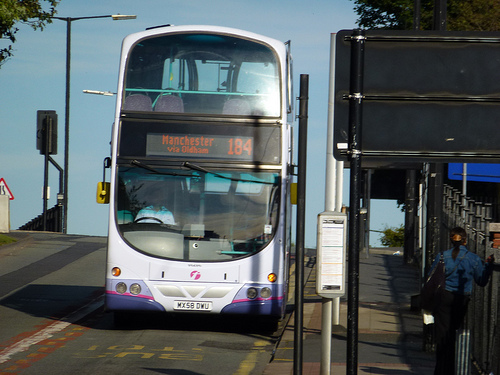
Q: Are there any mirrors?
A: Yes, there is a mirror.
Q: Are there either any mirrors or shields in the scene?
A: Yes, there is a mirror.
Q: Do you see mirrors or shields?
A: Yes, there is a mirror.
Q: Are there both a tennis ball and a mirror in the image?
A: No, there is a mirror but no tennis balls.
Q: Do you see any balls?
A: No, there are no balls.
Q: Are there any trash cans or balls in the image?
A: No, there are no balls or trash cans.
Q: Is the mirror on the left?
A: Yes, the mirror is on the left of the image.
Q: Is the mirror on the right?
A: No, the mirror is on the left of the image.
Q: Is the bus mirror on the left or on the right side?
A: The mirror is on the left of the image.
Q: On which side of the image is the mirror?
A: The mirror is on the left of the image.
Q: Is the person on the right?
A: Yes, the person is on the right of the image.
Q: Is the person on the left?
A: No, the person is on the right of the image.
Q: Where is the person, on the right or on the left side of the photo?
A: The person is on the right of the image.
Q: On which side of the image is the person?
A: The person is on the right of the image.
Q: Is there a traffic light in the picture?
A: Yes, there is a traffic light.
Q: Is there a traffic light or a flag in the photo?
A: Yes, there is a traffic light.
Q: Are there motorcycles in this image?
A: No, there are no motorcycles.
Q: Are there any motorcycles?
A: No, there are no motorcycles.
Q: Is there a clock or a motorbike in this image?
A: No, there are no motorcycles or clocks.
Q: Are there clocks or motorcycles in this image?
A: No, there are no motorcycles or clocks.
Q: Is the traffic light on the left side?
A: Yes, the traffic light is on the left of the image.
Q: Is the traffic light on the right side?
A: No, the traffic light is on the left of the image.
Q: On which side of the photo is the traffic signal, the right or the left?
A: The traffic signal is on the left of the image.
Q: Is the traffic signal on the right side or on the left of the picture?
A: The traffic signal is on the left of the image.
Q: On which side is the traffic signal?
A: The traffic signal is on the left of the image.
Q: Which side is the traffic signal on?
A: The traffic signal is on the left of the image.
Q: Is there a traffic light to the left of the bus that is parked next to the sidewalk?
A: Yes, there is a traffic light to the left of the bus.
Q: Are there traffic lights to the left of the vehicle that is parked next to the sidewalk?
A: Yes, there is a traffic light to the left of the bus.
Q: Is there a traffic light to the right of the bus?
A: No, the traffic light is to the left of the bus.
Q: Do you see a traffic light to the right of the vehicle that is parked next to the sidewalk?
A: No, the traffic light is to the left of the bus.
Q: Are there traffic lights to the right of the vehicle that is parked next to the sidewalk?
A: No, the traffic light is to the left of the bus.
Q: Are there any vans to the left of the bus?
A: No, there is a traffic light to the left of the bus.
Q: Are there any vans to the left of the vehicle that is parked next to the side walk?
A: No, there is a traffic light to the left of the bus.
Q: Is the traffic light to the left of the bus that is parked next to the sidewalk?
A: Yes, the traffic light is to the left of the bus.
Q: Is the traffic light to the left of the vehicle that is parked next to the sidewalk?
A: Yes, the traffic light is to the left of the bus.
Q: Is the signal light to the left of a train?
A: No, the signal light is to the left of the bus.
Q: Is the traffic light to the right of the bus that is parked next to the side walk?
A: No, the traffic light is to the left of the bus.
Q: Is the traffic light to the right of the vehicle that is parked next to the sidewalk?
A: No, the traffic light is to the left of the bus.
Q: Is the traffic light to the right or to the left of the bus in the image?
A: The traffic light is to the left of the bus.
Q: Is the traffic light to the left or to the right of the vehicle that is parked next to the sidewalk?
A: The traffic light is to the left of the bus.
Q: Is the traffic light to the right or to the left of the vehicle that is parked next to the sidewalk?
A: The traffic light is to the left of the bus.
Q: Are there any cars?
A: No, there are no cars.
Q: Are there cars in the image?
A: No, there are no cars.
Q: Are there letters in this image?
A: Yes, there are letters.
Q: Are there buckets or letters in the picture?
A: Yes, there are letters.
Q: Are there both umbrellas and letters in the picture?
A: No, there are letters but no umbrellas.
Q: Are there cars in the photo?
A: No, there are no cars.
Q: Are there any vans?
A: No, there are no vans.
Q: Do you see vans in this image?
A: No, there are no vans.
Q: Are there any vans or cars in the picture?
A: No, there are no vans or cars.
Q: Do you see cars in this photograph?
A: No, there are no cars.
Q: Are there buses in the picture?
A: Yes, there is a bus.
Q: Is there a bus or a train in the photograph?
A: Yes, there is a bus.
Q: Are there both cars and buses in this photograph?
A: No, there is a bus but no cars.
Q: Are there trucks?
A: No, there are no trucks.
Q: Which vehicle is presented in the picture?
A: The vehicle is a bus.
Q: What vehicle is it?
A: The vehicle is a bus.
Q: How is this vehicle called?
A: This is a bus.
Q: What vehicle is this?
A: This is a bus.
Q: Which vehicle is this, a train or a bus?
A: This is a bus.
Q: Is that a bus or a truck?
A: That is a bus.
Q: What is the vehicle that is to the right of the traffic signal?
A: The vehicle is a bus.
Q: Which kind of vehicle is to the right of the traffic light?
A: The vehicle is a bus.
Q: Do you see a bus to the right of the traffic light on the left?
A: Yes, there is a bus to the right of the traffic light.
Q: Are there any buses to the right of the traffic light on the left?
A: Yes, there is a bus to the right of the traffic light.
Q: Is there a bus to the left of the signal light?
A: No, the bus is to the right of the signal light.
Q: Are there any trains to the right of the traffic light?
A: No, there is a bus to the right of the traffic light.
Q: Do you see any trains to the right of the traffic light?
A: No, there is a bus to the right of the traffic light.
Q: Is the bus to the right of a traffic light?
A: Yes, the bus is to the right of a traffic light.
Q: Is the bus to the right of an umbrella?
A: No, the bus is to the right of a traffic light.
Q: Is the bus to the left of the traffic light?
A: No, the bus is to the right of the traffic light.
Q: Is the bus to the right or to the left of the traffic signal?
A: The bus is to the right of the traffic signal.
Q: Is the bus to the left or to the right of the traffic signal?
A: The bus is to the right of the traffic signal.